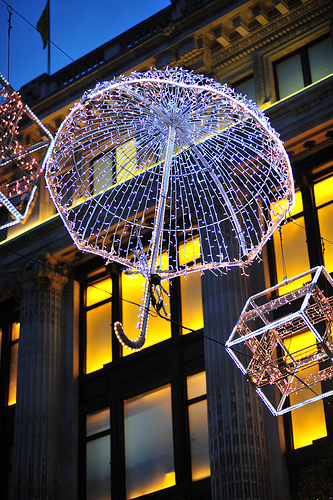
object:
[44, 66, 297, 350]
umbrella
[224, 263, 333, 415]
box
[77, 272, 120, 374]
window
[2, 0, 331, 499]
building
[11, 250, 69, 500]
pillar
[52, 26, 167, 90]
light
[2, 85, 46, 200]
light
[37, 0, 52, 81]
flag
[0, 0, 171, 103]
sky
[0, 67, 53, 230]
structure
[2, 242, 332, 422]
wire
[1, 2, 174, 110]
fence